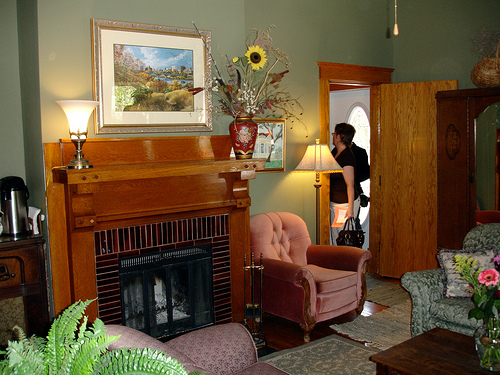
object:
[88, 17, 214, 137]
picture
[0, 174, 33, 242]
thermos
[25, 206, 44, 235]
coffee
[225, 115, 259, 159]
vase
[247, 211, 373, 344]
chair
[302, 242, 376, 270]
pink arm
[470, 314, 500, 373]
vase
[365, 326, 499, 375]
table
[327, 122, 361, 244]
person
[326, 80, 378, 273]
doorway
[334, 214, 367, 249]
pocket book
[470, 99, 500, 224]
mirror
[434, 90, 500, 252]
furniture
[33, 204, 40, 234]
napkin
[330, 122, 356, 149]
head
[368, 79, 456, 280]
door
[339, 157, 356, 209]
arm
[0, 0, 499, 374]
room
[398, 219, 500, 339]
couch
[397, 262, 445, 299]
arm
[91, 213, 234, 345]
fireplace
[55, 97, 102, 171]
lamp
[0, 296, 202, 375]
fern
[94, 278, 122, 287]
bricks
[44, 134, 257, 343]
mantel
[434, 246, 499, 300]
pillow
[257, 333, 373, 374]
rug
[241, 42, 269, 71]
flowers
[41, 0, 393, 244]
wall